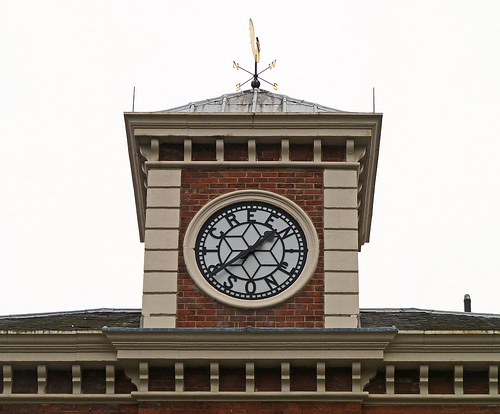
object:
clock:
[181, 187, 320, 312]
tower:
[123, 17, 381, 328]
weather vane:
[230, 18, 278, 93]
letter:
[256, 275, 288, 291]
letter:
[203, 242, 226, 262]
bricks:
[194, 309, 215, 316]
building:
[0, 308, 499, 413]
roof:
[356, 308, 499, 330]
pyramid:
[142, 87, 355, 114]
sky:
[0, 0, 499, 317]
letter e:
[245, 203, 257, 223]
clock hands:
[210, 246, 252, 276]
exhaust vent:
[461, 295, 469, 315]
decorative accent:
[387, 329, 499, 361]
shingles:
[322, 164, 359, 188]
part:
[314, 182, 324, 188]